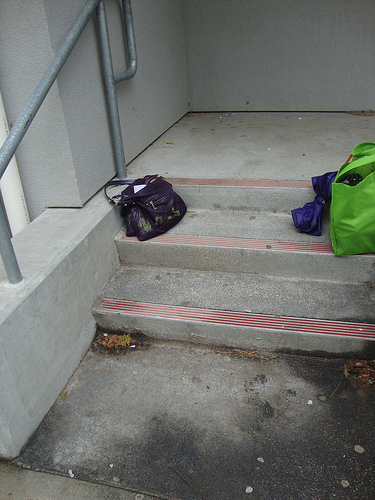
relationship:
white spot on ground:
[237, 483, 258, 493] [0, 324, 373, 498]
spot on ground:
[241, 483, 259, 494] [243, 484, 251, 494]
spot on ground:
[110, 473, 123, 483] [0, 324, 373, 498]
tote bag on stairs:
[323, 137, 363, 263] [86, 166, 364, 371]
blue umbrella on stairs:
[291, 167, 327, 237] [99, 226, 372, 356]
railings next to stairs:
[45, 10, 144, 111] [168, 170, 268, 301]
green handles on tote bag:
[334, 142, 373, 182] [329, 135, 374, 260]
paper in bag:
[128, 181, 149, 194] [99, 170, 192, 246]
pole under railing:
[90, 0, 134, 182] [0, 1, 141, 288]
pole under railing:
[2, 192, 28, 287] [0, 1, 141, 288]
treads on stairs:
[93, 293, 362, 347] [209, 167, 274, 353]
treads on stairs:
[117, 220, 334, 266] [209, 167, 274, 353]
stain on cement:
[273, 442, 363, 490] [122, 359, 193, 400]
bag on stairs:
[104, 171, 187, 242] [124, 221, 336, 257]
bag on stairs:
[329, 139, 375, 254] [124, 221, 336, 257]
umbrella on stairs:
[273, 154, 360, 239] [124, 221, 336, 257]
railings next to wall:
[0, 0, 142, 178] [21, 23, 204, 211]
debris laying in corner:
[86, 319, 147, 366] [85, 292, 117, 346]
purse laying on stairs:
[99, 167, 189, 243] [118, 174, 373, 258]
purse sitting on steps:
[99, 167, 189, 243] [92, 156, 372, 363]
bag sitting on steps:
[314, 113, 373, 254] [92, 156, 372, 363]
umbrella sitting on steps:
[288, 164, 336, 237] [92, 156, 372, 363]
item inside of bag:
[329, 142, 374, 256] [336, 173, 363, 186]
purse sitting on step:
[99, 167, 189, 243] [114, 183, 373, 290]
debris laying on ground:
[93, 332, 136, 349] [0, 324, 373, 498]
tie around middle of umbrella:
[313, 190, 328, 209] [290, 151, 356, 238]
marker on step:
[98, 290, 373, 341] [87, 258, 374, 364]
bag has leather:
[106, 166, 194, 243] [115, 177, 183, 233]